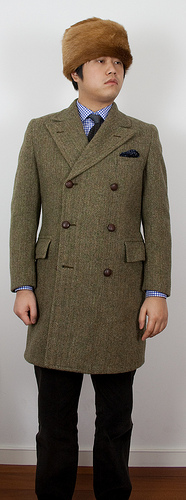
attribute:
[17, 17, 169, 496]
man — dressed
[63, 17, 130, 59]
cap — brown, large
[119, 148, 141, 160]
pocket square — black, dark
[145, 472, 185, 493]
floor — wooden, wood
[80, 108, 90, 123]
shirt — blue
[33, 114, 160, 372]
peacoat — couble breasted, brown, beige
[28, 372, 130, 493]
pants — loose, black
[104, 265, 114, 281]
button — brown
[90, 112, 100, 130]
tie — black, dark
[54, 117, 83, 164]
lapel — large